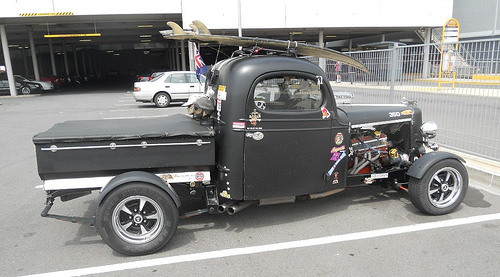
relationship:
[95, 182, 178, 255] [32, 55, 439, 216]
wheel on truck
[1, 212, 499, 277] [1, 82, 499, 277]
line on pavement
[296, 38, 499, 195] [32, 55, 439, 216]
rail near truck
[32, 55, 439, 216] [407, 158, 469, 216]
truck has wheel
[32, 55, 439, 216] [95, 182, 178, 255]
truck has wheel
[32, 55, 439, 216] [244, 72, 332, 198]
truck has door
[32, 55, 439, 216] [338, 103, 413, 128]
truck has hood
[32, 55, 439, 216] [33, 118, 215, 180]
truck has bed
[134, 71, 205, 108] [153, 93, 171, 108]
car has wheel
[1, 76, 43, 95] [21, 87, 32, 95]
car has wheel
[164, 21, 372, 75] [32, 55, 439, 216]
surfboard on truck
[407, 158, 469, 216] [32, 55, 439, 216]
wheel on truck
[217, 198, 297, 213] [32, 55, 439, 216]
muffler on truck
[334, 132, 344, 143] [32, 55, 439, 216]
sticker on truck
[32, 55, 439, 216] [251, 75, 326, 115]
truck has window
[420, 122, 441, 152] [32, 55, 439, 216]
headlight on truck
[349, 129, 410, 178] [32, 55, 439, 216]
engine in truck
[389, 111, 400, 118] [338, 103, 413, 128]
number on hood